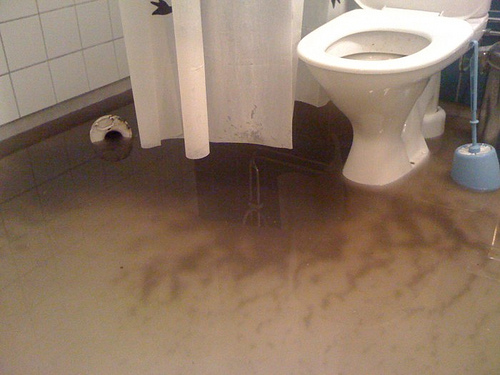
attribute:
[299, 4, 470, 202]
toilet — white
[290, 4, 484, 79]
seat — white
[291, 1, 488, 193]
toilet — white